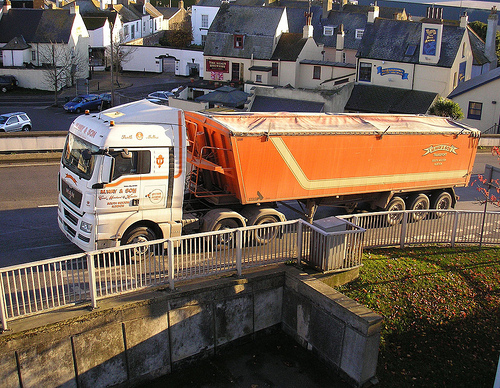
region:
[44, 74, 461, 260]
white truck on the street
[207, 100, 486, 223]
orange bed of truck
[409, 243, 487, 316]
green grass next to gate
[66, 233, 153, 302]
white gate next to vehicle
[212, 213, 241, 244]
tire on a car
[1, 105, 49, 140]
car on the road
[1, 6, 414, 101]
buildings next to the road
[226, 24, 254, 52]
window on a building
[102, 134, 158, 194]
window on a door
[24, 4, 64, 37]
roof of the house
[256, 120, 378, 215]
orange design on truck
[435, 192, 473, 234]
back wheel of truck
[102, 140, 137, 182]
left view mirror of truck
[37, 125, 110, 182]
front window of truck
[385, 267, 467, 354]
green grass in front of house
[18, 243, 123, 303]
white fence in front of house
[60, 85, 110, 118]
sporty car on road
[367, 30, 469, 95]
dirty beige house behind truck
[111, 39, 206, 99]
white building in background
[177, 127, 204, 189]
ladder of orange truck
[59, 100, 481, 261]
a big diesel truck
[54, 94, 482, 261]
an 18-wheeler truck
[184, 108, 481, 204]
an orange cargo container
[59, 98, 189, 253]
white cab with an orange stripe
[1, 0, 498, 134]
a neighborhood in the background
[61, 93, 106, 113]
a small blue car in the background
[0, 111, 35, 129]
a grey suv in the background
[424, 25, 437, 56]
a blue sign on chimney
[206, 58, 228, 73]
a red sign on house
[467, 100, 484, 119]
a closed window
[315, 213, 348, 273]
a public trashcan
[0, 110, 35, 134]
a small SUV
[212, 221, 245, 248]
the wheel of a truck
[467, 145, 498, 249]
a small tree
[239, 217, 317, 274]
a white iron rail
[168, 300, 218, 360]
a cement retaining wall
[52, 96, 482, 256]
a large orange truck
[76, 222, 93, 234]
the headlight of a truck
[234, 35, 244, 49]
a window of a building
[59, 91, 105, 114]
a small blue car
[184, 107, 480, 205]
orange and white rig attached to a white truck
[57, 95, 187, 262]
white and orange industrial truck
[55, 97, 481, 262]
white truck pulling an orange rig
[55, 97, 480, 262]
industrial white truck carrying materials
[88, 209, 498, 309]
white metal fence beside the bridge ramp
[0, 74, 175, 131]
four cars in a parking lot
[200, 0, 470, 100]
two commercial business establishments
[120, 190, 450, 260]
six tires on the left side of industrial truck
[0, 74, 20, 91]
back side of a small SUV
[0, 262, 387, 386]
cement retaining wall below a metal fence